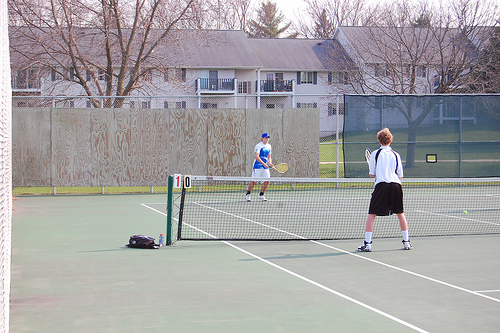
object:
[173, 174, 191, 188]
numbers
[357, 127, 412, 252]
man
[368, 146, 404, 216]
black and white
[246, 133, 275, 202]
man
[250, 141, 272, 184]
blue and white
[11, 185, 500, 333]
court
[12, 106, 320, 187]
boards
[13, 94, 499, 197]
fence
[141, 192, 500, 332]
lines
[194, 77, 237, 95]
balcony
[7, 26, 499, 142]
building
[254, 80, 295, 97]
balcony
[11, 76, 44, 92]
balcony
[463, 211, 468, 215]
tennis ball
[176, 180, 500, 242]
net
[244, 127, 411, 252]
tennis players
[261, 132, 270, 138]
hat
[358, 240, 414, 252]
shoes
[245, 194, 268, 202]
shoes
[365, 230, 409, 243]
socks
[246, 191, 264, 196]
socks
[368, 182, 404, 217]
shorts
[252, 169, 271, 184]
shorts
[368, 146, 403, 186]
shirt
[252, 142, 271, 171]
shirt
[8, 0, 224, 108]
tree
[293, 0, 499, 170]
tree